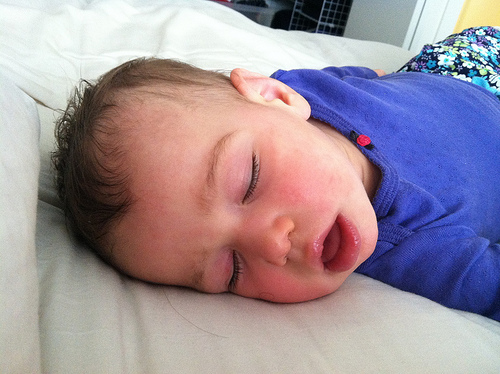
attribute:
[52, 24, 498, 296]
baby — laying, sleeping, rosy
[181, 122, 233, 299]
eyebrows — bushy, brown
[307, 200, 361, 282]
mouth — open, grooved, red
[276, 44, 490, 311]
shirt — blue, wrinkled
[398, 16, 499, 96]
shorts — floral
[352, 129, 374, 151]
dot — red, pink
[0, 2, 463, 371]
sheet — white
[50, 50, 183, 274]
hair — brown, dark